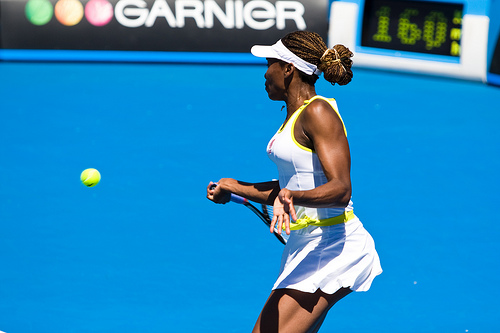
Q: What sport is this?
A: Lawn tennis.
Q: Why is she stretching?
A: To hit the ball.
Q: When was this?
A: Daytime.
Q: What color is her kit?
A: White.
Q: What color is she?
A: Black.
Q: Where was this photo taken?
A: On the tennis court.